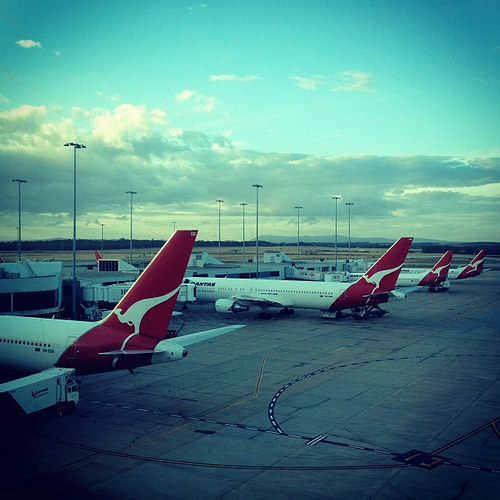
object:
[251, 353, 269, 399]
line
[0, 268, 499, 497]
tarmac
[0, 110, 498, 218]
cloud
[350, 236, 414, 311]
tail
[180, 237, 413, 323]
plane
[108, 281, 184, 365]
logo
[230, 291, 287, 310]
wing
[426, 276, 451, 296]
truck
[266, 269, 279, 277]
window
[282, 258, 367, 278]
building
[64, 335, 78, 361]
door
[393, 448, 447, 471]
box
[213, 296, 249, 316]
engine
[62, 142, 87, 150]
light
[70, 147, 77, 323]
pole